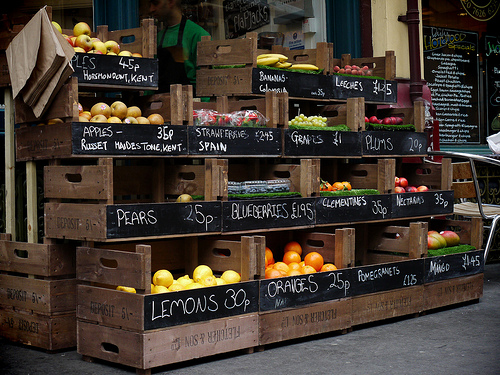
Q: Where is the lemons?
A: Bin.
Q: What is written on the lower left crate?
A: Lemons.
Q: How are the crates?
A: Stacked.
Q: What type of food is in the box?
A: Fruits.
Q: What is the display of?
A: Crates of fruits.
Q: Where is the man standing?
A: Behind the crates.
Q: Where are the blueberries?
A: Above the oranges.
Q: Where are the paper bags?
A: On the side of the apples.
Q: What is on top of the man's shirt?
A: An apron.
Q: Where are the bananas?
A: On the top.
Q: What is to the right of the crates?
A: A chair.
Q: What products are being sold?
A: Fruits.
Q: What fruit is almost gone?
A: Pears.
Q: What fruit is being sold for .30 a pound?
A: Lemons.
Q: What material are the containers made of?
A: Wood.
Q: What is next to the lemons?
A: Oranges.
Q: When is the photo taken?
A: Daytime.